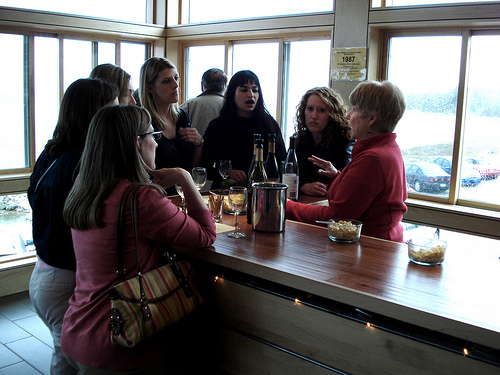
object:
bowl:
[407, 237, 448, 266]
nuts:
[411, 247, 444, 263]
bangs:
[233, 71, 260, 87]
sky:
[396, 39, 453, 70]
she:
[59, 104, 217, 375]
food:
[409, 245, 445, 263]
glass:
[174, 184, 187, 211]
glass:
[190, 166, 207, 191]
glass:
[218, 157, 233, 180]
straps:
[115, 182, 179, 277]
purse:
[106, 184, 205, 351]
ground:
[0, 306, 33, 375]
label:
[282, 173, 299, 201]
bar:
[158, 194, 498, 373]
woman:
[203, 69, 287, 190]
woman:
[287, 86, 350, 198]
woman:
[26, 78, 120, 375]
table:
[175, 194, 499, 375]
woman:
[283, 81, 408, 248]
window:
[182, 46, 219, 100]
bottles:
[281, 137, 298, 202]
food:
[329, 220, 360, 239]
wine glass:
[228, 186, 249, 239]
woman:
[131, 57, 205, 197]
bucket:
[250, 181, 290, 233]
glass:
[227, 185, 248, 238]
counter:
[176, 190, 500, 375]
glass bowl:
[407, 238, 448, 266]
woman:
[180, 67, 227, 135]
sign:
[328, 46, 368, 82]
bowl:
[222, 194, 249, 215]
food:
[223, 194, 246, 211]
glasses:
[137, 130, 163, 141]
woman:
[88, 63, 139, 106]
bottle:
[247, 139, 271, 223]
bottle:
[263, 133, 282, 183]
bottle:
[247, 132, 262, 178]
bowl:
[327, 219, 363, 244]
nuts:
[330, 221, 358, 237]